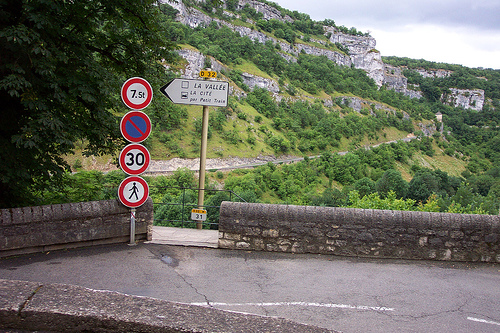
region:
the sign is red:
[93, 61, 205, 218]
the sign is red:
[89, 44, 254, 330]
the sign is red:
[69, 99, 202, 285]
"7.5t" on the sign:
[115, 77, 155, 109]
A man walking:
[121, 180, 158, 212]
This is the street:
[108, 242, 427, 321]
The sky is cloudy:
[356, 8, 481, 134]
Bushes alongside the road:
[240, 146, 462, 203]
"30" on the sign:
[113, 141, 163, 175]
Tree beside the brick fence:
[7, 3, 147, 189]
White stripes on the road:
[223, 238, 450, 330]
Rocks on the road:
[233, 34, 442, 189]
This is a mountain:
[176, 1, 489, 202]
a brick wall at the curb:
[217, 198, 497, 266]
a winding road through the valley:
[210, 129, 423, 176]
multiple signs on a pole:
[120, 76, 151, 244]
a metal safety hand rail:
[150, 183, 230, 223]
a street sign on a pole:
[160, 68, 227, 227]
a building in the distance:
[433, 109, 445, 136]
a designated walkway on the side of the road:
[0, 242, 499, 331]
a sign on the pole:
[191, 207, 206, 222]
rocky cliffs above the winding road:
[227, 14, 498, 189]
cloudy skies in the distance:
[374, 1, 499, 64]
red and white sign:
[117, 73, 156, 110]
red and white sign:
[115, 141, 154, 175]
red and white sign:
[111, 173, 153, 214]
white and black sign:
[159, 78, 235, 110]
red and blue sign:
[115, 103, 157, 143]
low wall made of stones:
[209, 189, 499, 274]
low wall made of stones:
[0, 187, 155, 273]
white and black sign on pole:
[156, 64, 232, 230]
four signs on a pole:
[102, 68, 164, 259]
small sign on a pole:
[181, 205, 211, 226]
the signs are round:
[113, 72, 160, 217]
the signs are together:
[117, 75, 157, 213]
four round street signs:
[114, 67, 154, 208]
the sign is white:
[158, 75, 234, 114]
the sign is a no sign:
[115, 107, 158, 147]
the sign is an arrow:
[155, 76, 241, 113]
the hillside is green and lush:
[0, 0, 499, 242]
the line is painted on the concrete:
[186, 296, 498, 331]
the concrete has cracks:
[137, 240, 481, 325]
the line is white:
[186, 296, 498, 328]